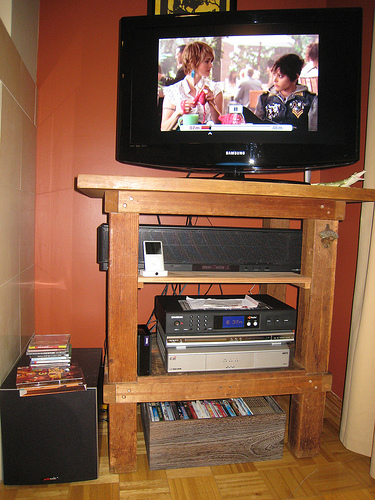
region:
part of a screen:
[225, 39, 270, 74]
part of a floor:
[261, 467, 292, 497]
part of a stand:
[114, 431, 135, 462]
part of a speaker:
[39, 420, 76, 453]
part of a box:
[201, 420, 231, 454]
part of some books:
[190, 403, 205, 416]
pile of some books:
[32, 342, 62, 377]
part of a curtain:
[337, 400, 355, 436]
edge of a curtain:
[344, 435, 365, 455]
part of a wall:
[332, 345, 343, 369]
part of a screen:
[208, 46, 290, 101]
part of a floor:
[282, 461, 318, 493]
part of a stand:
[103, 436, 136, 478]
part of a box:
[192, 440, 230, 471]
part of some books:
[181, 410, 201, 418]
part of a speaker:
[60, 437, 93, 474]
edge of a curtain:
[335, 425, 363, 458]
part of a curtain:
[330, 371, 361, 419]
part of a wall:
[67, 287, 96, 327]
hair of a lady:
[185, 45, 206, 64]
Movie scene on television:
[141, 24, 333, 148]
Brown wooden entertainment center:
[110, 166, 364, 471]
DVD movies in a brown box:
[138, 395, 276, 476]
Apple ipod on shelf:
[104, 212, 206, 292]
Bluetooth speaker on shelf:
[85, 215, 343, 283]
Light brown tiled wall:
[5, 77, 67, 258]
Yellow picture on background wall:
[125, 1, 261, 54]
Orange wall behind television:
[43, 6, 182, 188]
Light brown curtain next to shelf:
[319, 179, 373, 466]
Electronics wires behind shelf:
[129, 163, 262, 355]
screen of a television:
[240, 81, 300, 123]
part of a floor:
[271, 466, 307, 494]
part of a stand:
[110, 423, 138, 453]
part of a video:
[215, 305, 260, 332]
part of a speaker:
[38, 430, 89, 485]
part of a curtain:
[342, 421, 359, 454]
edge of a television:
[262, 160, 292, 178]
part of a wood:
[210, 373, 238, 393]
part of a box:
[224, 430, 270, 473]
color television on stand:
[115, 3, 360, 183]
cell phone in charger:
[140, 235, 169, 279]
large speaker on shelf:
[92, 220, 311, 275]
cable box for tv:
[152, 291, 299, 338]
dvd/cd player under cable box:
[154, 345, 292, 372]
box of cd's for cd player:
[141, 395, 283, 467]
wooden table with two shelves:
[73, 173, 373, 476]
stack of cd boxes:
[27, 330, 73, 375]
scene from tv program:
[155, 36, 320, 136]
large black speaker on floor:
[7, 338, 101, 488]